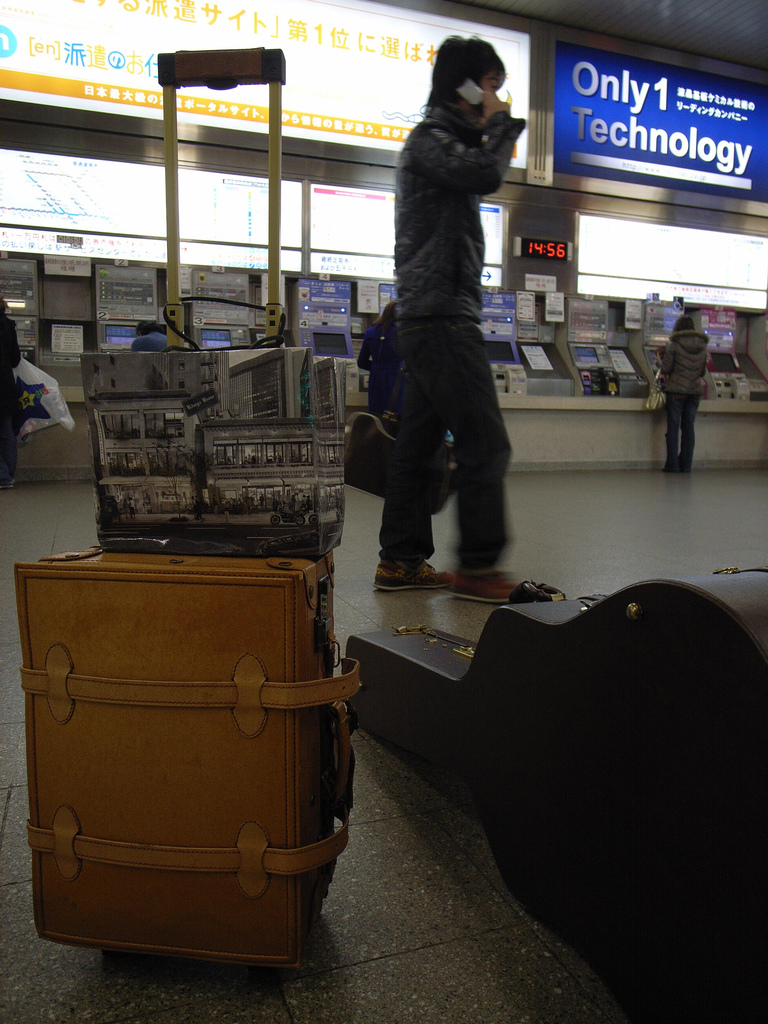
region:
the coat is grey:
[397, 117, 499, 291]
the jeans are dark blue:
[396, 317, 513, 551]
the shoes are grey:
[370, 553, 512, 600]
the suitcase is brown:
[21, 549, 344, 986]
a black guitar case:
[347, 557, 762, 1007]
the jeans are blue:
[667, 388, 703, 457]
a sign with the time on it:
[517, 231, 586, 263]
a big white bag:
[8, 365, 67, 435]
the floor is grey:
[29, 456, 760, 598]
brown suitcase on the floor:
[4, 543, 359, 975]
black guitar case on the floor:
[345, 598, 764, 935]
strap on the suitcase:
[255, 662, 364, 711]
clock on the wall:
[516, 231, 574, 260]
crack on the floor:
[379, 912, 506, 963]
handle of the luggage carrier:
[142, 46, 296, 345]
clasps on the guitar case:
[390, 617, 432, 644]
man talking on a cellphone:
[364, 17, 537, 588]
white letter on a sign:
[568, 56, 600, 100]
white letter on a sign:
[596, 71, 624, 103]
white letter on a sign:
[620, 61, 634, 104]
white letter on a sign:
[627, 76, 648, 115]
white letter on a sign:
[565, 98, 595, 144]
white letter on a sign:
[583, 111, 615, 145]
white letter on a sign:
[608, 109, 629, 145]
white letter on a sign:
[647, 122, 673, 157]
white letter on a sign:
[669, 122, 696, 153]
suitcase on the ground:
[34, 531, 303, 950]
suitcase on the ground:
[362, 602, 575, 917]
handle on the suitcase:
[236, 825, 278, 919]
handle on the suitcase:
[49, 803, 91, 877]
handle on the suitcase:
[114, 539, 173, 558]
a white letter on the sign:
[568, 58, 607, 108]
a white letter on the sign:
[607, 73, 622, 97]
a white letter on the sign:
[605, 60, 626, 110]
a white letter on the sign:
[658, 71, 671, 103]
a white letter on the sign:
[566, 106, 590, 132]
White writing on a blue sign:
[550, 54, 757, 187]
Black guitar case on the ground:
[338, 553, 763, 960]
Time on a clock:
[511, 231, 574, 263]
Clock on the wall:
[511, 232, 582, 271]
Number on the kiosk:
[294, 313, 315, 331]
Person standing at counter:
[645, 315, 706, 477]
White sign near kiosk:
[46, 318, 93, 360]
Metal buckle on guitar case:
[387, 620, 440, 644]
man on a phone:
[341, 30, 641, 611]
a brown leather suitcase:
[25, 523, 371, 1001]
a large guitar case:
[352, 474, 755, 1010]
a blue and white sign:
[539, 39, 760, 201]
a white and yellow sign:
[10, 13, 465, 149]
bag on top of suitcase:
[56, 299, 365, 565]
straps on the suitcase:
[268, 627, 377, 908]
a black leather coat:
[378, 110, 556, 326]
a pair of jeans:
[376, 281, 539, 598]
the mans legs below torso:
[366, 304, 530, 562]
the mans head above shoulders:
[415, 21, 510, 127]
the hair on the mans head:
[420, 25, 494, 88]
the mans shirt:
[373, 107, 534, 319]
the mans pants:
[360, 297, 523, 564]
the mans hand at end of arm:
[469, 83, 513, 133]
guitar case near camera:
[337, 551, 760, 1010]